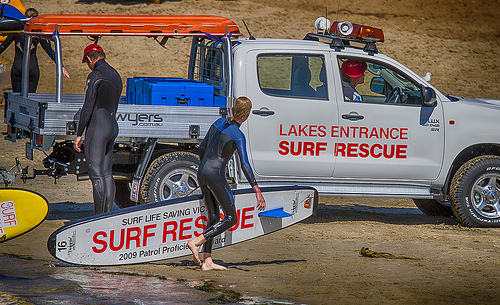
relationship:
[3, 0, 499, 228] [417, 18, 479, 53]
vehicle on beach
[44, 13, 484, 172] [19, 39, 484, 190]
vehicle a pickup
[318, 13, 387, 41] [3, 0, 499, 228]
light on vehicle